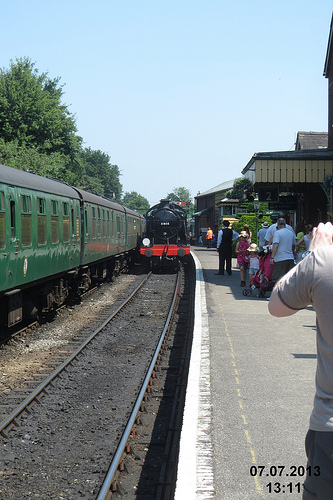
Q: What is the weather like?
A: It is clear.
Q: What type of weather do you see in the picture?
A: It is clear.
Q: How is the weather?
A: It is clear.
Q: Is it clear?
A: Yes, it is clear.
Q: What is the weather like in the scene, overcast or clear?
A: It is clear.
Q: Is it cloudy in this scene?
A: No, it is clear.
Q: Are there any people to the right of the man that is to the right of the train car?
A: Yes, there is a person to the right of the man.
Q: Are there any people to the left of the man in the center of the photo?
A: No, the person is to the right of the man.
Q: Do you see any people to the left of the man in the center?
A: No, the person is to the right of the man.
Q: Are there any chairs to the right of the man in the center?
A: No, there is a person to the right of the man.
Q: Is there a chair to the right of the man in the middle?
A: No, there is a person to the right of the man.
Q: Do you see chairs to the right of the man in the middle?
A: No, there is a person to the right of the man.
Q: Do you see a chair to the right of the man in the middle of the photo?
A: No, there is a person to the right of the man.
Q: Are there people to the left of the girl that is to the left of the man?
A: Yes, there is a person to the left of the girl.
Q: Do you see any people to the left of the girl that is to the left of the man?
A: Yes, there is a person to the left of the girl.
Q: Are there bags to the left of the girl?
A: No, there is a person to the left of the girl.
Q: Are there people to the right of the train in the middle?
A: Yes, there is a person to the right of the train.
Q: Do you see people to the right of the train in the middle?
A: Yes, there is a person to the right of the train.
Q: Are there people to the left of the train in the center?
A: No, the person is to the right of the train.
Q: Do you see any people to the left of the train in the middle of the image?
A: No, the person is to the right of the train.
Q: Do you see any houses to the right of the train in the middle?
A: No, there is a person to the right of the train.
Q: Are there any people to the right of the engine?
A: Yes, there is a person to the right of the engine.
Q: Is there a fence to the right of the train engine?
A: No, there is a person to the right of the train engine.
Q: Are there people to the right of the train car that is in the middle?
A: Yes, there is a person to the right of the train car.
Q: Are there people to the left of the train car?
A: No, the person is to the right of the train car.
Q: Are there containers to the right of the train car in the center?
A: No, there is a person to the right of the train car.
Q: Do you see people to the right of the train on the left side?
A: Yes, there is a person to the right of the train.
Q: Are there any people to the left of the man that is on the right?
A: Yes, there is a person to the left of the man.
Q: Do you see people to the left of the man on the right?
A: Yes, there is a person to the left of the man.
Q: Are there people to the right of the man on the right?
A: No, the person is to the left of the man.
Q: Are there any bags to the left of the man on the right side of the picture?
A: No, there is a person to the left of the man.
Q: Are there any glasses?
A: No, there are no glasses.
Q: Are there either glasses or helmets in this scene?
A: No, there are no glasses or helmets.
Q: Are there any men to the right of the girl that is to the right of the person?
A: Yes, there is a man to the right of the girl.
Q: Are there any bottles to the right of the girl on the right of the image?
A: No, there is a man to the right of the girl.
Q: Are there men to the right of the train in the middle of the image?
A: Yes, there is a man to the right of the train.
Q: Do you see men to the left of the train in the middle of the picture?
A: No, the man is to the right of the train.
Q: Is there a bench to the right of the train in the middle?
A: No, there is a man to the right of the train.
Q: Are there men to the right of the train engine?
A: Yes, there is a man to the right of the train engine.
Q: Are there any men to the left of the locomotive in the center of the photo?
A: No, the man is to the right of the train engine.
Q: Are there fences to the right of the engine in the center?
A: No, there is a man to the right of the train engine.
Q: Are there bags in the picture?
A: No, there are no bags.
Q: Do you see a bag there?
A: No, there are no bags.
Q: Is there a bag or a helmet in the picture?
A: No, there are no bags or helmets.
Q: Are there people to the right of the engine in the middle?
A: Yes, there is a person to the right of the engine.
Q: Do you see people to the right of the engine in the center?
A: Yes, there is a person to the right of the engine.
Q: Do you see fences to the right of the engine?
A: No, there is a person to the right of the engine.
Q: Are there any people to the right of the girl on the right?
A: Yes, there is a person to the right of the girl.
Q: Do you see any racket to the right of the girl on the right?
A: No, there is a person to the right of the girl.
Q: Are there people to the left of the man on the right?
A: Yes, there is a person to the left of the man.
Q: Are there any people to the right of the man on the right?
A: No, the person is to the left of the man.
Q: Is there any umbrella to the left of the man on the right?
A: No, there is a person to the left of the man.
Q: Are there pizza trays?
A: No, there are no pizza trays.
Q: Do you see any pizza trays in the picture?
A: No, there are no pizza trays.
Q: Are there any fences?
A: No, there are no fences.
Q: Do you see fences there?
A: No, there are no fences.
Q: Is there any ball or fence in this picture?
A: No, there are no fences or balls.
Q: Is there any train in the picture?
A: Yes, there is a train.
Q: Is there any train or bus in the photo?
A: Yes, there is a train.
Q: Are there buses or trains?
A: Yes, there is a train.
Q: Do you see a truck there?
A: No, there are no trucks.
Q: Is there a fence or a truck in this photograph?
A: No, there are no trucks or fences.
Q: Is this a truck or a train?
A: This is a train.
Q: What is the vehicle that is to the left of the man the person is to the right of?
A: The vehicle is a train.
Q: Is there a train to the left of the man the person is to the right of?
A: Yes, there is a train to the left of the man.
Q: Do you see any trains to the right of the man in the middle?
A: No, the train is to the left of the man.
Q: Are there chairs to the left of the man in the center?
A: No, there is a train to the left of the man.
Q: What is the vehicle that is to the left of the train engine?
A: The vehicle is a train.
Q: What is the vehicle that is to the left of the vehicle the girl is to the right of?
A: The vehicle is a train.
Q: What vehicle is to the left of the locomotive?
A: The vehicle is a train.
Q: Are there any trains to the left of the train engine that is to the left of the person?
A: Yes, there is a train to the left of the locomotive.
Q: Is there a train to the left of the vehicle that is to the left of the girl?
A: Yes, there is a train to the left of the locomotive.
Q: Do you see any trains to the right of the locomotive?
A: No, the train is to the left of the locomotive.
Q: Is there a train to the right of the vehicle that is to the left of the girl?
A: No, the train is to the left of the locomotive.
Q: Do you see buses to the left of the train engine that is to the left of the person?
A: No, there is a train to the left of the locomotive.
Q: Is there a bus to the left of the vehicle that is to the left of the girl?
A: No, there is a train to the left of the locomotive.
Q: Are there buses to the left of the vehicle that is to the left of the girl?
A: No, there is a train to the left of the locomotive.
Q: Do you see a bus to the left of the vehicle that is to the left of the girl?
A: No, there is a train to the left of the locomotive.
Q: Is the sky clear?
A: Yes, the sky is clear.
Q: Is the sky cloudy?
A: No, the sky is clear.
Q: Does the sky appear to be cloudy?
A: No, the sky is clear.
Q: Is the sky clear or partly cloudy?
A: The sky is clear.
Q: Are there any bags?
A: No, there are no bags.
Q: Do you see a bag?
A: No, there are no bags.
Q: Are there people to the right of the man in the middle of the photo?
A: Yes, there is a person to the right of the man.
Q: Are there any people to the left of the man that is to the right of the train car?
A: No, the person is to the right of the man.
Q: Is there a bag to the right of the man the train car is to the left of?
A: No, there is a person to the right of the man.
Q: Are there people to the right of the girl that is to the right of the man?
A: Yes, there is a person to the right of the girl.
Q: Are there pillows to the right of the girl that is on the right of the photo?
A: No, there is a person to the right of the girl.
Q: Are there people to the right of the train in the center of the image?
A: Yes, there is a person to the right of the train.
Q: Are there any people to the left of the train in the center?
A: No, the person is to the right of the train.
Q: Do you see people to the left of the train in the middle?
A: No, the person is to the right of the train.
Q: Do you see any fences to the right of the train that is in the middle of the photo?
A: No, there is a person to the right of the train.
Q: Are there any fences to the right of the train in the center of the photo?
A: No, there is a person to the right of the train.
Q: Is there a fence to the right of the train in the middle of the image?
A: No, there is a person to the right of the train.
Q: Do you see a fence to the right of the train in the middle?
A: No, there is a person to the right of the train.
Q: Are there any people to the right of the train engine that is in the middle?
A: Yes, there is a person to the right of the locomotive.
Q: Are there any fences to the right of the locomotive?
A: No, there is a person to the right of the locomotive.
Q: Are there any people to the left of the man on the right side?
A: Yes, there is a person to the left of the man.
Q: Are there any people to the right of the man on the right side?
A: No, the person is to the left of the man.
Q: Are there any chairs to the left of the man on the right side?
A: No, there is a person to the left of the man.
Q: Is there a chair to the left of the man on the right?
A: No, there is a person to the left of the man.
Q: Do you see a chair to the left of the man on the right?
A: No, there is a person to the left of the man.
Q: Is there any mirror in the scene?
A: No, there are no mirrors.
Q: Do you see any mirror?
A: No, there are no mirrors.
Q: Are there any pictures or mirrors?
A: No, there are no mirrors or pictures.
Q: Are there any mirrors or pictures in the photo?
A: No, there are no mirrors or pictures.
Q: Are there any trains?
A: Yes, there is a train.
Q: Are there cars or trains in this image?
A: Yes, there is a train.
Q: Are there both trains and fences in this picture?
A: No, there is a train but no fences.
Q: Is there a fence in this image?
A: No, there are no fences.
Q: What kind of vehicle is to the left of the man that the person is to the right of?
A: The vehicle is a train.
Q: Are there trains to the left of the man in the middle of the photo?
A: Yes, there is a train to the left of the man.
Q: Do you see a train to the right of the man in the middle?
A: No, the train is to the left of the man.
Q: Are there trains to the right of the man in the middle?
A: No, the train is to the left of the man.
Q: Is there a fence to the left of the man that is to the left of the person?
A: No, there is a train to the left of the man.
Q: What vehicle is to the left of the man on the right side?
A: The vehicle is a train.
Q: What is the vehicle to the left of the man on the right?
A: The vehicle is a train.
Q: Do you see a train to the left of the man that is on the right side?
A: Yes, there is a train to the left of the man.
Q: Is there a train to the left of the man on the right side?
A: Yes, there is a train to the left of the man.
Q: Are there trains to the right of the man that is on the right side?
A: No, the train is to the left of the man.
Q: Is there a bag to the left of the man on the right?
A: No, there is a train to the left of the man.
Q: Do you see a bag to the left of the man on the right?
A: No, there is a train to the left of the man.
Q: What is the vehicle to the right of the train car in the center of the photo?
A: The vehicle is a train.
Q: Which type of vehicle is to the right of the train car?
A: The vehicle is a train.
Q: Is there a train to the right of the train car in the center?
A: Yes, there is a train to the right of the train car.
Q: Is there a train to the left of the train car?
A: No, the train is to the right of the train car.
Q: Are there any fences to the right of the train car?
A: No, there is a train to the right of the train car.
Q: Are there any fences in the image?
A: No, there are no fences.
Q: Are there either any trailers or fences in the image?
A: No, there are no fences or trailers.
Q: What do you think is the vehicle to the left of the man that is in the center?
A: The vehicle is a locomotive.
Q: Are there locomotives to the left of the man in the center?
A: Yes, there is a locomotive to the left of the man.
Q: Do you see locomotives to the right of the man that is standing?
A: No, the locomotive is to the left of the man.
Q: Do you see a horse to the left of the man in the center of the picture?
A: No, there is a locomotive to the left of the man.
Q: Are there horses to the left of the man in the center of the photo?
A: No, there is a locomotive to the left of the man.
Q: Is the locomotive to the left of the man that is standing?
A: Yes, the locomotive is to the left of the man.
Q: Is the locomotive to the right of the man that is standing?
A: No, the locomotive is to the left of the man.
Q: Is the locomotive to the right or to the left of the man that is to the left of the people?
A: The locomotive is to the left of the man.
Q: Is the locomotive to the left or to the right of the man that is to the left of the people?
A: The locomotive is to the left of the man.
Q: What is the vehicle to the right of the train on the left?
A: The vehicle is a locomotive.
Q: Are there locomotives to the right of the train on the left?
A: Yes, there is a locomotive to the right of the train.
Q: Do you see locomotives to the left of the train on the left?
A: No, the locomotive is to the right of the train.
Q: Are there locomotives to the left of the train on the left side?
A: No, the locomotive is to the right of the train.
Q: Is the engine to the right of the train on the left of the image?
A: Yes, the engine is to the right of the train.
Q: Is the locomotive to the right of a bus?
A: No, the locomotive is to the right of the train.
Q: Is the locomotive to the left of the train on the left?
A: No, the locomotive is to the right of the train.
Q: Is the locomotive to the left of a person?
A: Yes, the locomotive is to the left of a person.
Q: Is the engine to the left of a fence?
A: No, the engine is to the left of a person.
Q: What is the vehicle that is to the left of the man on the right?
A: The vehicle is a locomotive.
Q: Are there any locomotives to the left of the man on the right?
A: Yes, there is a locomotive to the left of the man.